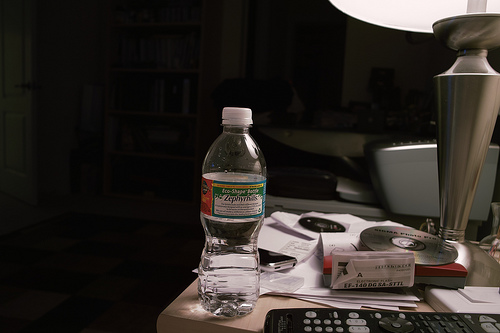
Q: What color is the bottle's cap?
A: White.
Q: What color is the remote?
A: Black.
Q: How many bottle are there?
A: One.